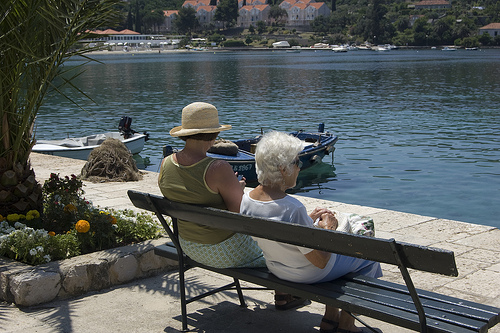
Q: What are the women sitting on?
A: A bench.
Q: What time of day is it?
A: Afternoon.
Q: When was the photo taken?
A: Daytime.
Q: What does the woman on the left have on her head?
A: A hat.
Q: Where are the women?
A: Sitting on a bench.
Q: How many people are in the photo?
A: Two.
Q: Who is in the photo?
A: Two women.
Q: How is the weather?
A: Sunny.